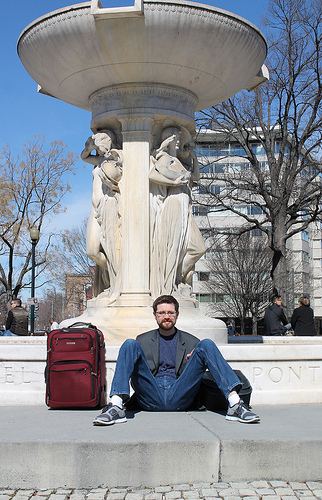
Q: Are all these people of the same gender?
A: No, they are both male and female.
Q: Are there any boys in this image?
A: No, there are no boys.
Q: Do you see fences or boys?
A: No, there are no boys or fences.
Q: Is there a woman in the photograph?
A: Yes, there is a woman.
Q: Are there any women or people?
A: Yes, there is a woman.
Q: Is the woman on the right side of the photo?
A: Yes, the woman is on the right of the image.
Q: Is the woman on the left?
A: No, the woman is on the right of the image.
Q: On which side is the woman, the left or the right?
A: The woman is on the right of the image.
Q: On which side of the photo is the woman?
A: The woman is on the right of the image.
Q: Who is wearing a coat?
A: The woman is wearing a coat.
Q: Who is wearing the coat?
A: The woman is wearing a coat.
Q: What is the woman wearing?
A: The woman is wearing a coat.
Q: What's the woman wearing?
A: The woman is wearing a coat.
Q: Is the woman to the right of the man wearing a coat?
A: Yes, the woman is wearing a coat.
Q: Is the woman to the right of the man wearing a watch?
A: No, the woman is wearing a coat.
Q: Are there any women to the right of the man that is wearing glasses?
A: Yes, there is a woman to the right of the man.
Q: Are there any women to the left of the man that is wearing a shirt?
A: No, the woman is to the right of the man.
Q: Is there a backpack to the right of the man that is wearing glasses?
A: No, there is a woman to the right of the man.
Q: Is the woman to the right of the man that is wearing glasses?
A: Yes, the woman is to the right of the man.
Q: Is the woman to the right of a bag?
A: No, the woman is to the right of the man.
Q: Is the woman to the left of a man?
A: No, the woman is to the right of a man.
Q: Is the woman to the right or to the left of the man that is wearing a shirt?
A: The woman is to the right of the man.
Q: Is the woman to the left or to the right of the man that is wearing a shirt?
A: The woman is to the right of the man.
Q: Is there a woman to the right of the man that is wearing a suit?
A: Yes, there is a woman to the right of the man.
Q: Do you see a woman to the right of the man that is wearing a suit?
A: Yes, there is a woman to the right of the man.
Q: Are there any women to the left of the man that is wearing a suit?
A: No, the woman is to the right of the man.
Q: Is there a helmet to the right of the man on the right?
A: No, there is a woman to the right of the man.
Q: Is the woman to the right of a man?
A: Yes, the woman is to the right of a man.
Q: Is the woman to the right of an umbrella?
A: No, the woman is to the right of a man.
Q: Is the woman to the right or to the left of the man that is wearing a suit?
A: The woman is to the right of the man.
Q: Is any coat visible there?
A: Yes, there is a coat.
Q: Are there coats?
A: Yes, there is a coat.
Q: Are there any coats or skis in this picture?
A: Yes, there is a coat.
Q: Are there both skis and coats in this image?
A: No, there is a coat but no skis.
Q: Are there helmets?
A: No, there are no helmets.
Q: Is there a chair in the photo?
A: No, there are no chairs.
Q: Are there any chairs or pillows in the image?
A: No, there are no chairs or pillows.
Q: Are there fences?
A: No, there are no fences.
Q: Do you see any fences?
A: No, there are no fences.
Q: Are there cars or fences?
A: No, there are no fences or cars.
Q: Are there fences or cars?
A: No, there are no fences or cars.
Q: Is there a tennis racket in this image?
A: No, there are no rackets.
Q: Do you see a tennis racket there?
A: No, there are no rackets.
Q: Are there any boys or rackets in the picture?
A: No, there are no rackets or boys.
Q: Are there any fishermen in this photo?
A: No, there are no fishermen.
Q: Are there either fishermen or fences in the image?
A: No, there are no fishermen or fences.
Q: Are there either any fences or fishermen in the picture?
A: No, there are no fishermen or fences.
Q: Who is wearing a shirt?
A: The man is wearing a shirt.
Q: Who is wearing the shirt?
A: The man is wearing a shirt.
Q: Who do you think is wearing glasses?
A: The man is wearing glasses.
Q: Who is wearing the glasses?
A: The man is wearing glasses.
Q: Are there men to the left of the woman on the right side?
A: Yes, there is a man to the left of the woman.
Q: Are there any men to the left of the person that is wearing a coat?
A: Yes, there is a man to the left of the woman.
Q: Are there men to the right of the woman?
A: No, the man is to the left of the woman.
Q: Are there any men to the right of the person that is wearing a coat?
A: No, the man is to the left of the woman.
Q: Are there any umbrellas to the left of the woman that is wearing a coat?
A: No, there is a man to the left of the woman.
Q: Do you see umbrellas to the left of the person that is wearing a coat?
A: No, there is a man to the left of the woman.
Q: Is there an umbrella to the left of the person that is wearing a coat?
A: No, there is a man to the left of the woman.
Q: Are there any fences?
A: No, there are no fences.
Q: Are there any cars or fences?
A: No, there are no fences or cars.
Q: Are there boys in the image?
A: No, there are no boys.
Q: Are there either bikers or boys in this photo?
A: No, there are no boys or bikers.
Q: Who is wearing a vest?
A: The man is wearing a vest.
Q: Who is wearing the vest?
A: The man is wearing a vest.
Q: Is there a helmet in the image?
A: No, there are no helmets.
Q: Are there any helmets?
A: No, there are no helmets.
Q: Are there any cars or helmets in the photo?
A: No, there are no helmets or cars.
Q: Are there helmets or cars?
A: No, there are no helmets or cars.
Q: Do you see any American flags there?
A: No, there are no American flags.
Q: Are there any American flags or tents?
A: No, there are no American flags or tents.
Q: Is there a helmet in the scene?
A: No, there are no helmets.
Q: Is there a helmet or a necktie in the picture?
A: No, there are no helmets or ties.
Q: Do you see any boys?
A: No, there are no boys.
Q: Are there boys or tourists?
A: No, there are no boys or tourists.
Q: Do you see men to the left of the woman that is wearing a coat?
A: Yes, there is a man to the left of the woman.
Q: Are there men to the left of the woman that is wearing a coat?
A: Yes, there is a man to the left of the woman.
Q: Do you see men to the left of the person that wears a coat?
A: Yes, there is a man to the left of the woman.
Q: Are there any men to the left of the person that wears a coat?
A: Yes, there is a man to the left of the woman.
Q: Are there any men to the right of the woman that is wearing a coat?
A: No, the man is to the left of the woman.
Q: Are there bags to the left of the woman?
A: No, there is a man to the left of the woman.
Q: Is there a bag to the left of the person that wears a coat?
A: No, there is a man to the left of the woman.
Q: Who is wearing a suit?
A: The man is wearing a suit.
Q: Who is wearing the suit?
A: The man is wearing a suit.